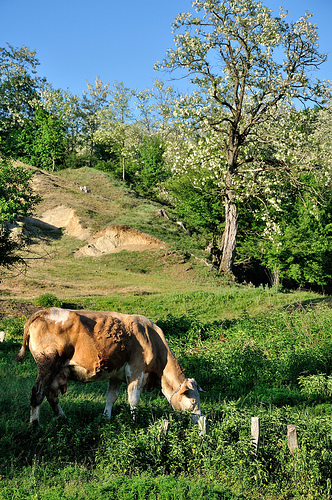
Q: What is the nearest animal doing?
A: Grazing.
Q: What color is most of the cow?
A: Brown.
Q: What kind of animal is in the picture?
A: A cow.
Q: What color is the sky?
A: Blue.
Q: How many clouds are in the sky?
A: 0.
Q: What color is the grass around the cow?
A: Green.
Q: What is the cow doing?
A: Eating grass.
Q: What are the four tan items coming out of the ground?
A: Pieces of wood.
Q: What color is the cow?
A: Brown and white.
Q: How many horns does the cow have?
A: 0.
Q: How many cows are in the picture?
A: 1.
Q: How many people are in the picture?
A: 0.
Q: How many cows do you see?
A: 1.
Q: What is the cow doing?
A: Grazing.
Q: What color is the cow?
A: Light brown.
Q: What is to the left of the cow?
A: Trees.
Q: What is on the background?
A: A dirt hill.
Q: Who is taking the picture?
A: A photographer.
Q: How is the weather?
A: Clear and warm.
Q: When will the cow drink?
A: When he's tired of eating.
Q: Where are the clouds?
A: There are none.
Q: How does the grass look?
A: Green and healthy.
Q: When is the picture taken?
A: In daytime.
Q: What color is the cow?
A: Brown with white patches.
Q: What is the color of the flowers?
A: White.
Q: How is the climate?
A: Sunny.